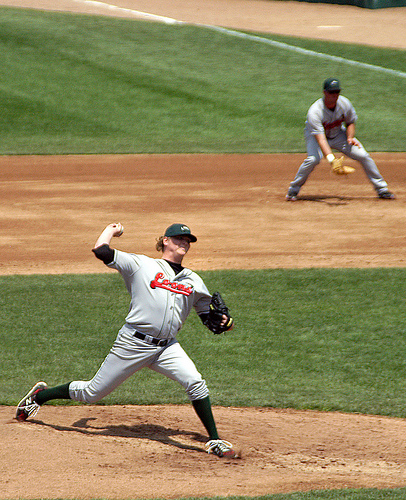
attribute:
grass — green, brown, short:
[2, 42, 296, 153]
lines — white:
[84, 0, 403, 80]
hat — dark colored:
[158, 220, 207, 248]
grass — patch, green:
[274, 323, 373, 377]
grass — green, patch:
[1, 270, 404, 408]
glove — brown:
[316, 154, 368, 180]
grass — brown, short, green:
[248, 275, 381, 406]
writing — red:
[150, 273, 193, 299]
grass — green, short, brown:
[0, 9, 404, 148]